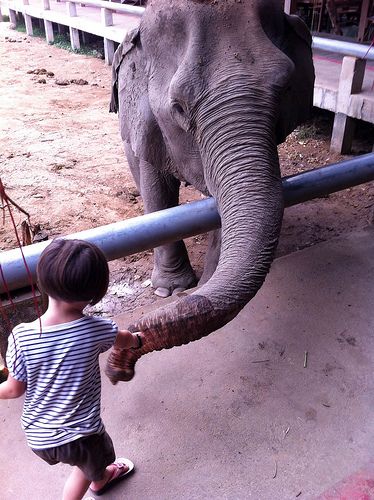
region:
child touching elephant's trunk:
[15, 229, 296, 460]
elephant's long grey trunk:
[93, 114, 319, 392]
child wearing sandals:
[87, 450, 144, 497]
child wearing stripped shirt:
[0, 319, 147, 449]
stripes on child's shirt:
[31, 345, 67, 392]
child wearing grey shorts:
[27, 433, 122, 476]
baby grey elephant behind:
[89, 2, 330, 300]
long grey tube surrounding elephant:
[0, 107, 369, 298]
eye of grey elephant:
[170, 94, 188, 122]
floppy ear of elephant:
[272, 10, 334, 146]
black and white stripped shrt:
[6, 316, 119, 438]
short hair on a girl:
[31, 239, 110, 309]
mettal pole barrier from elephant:
[6, 140, 372, 267]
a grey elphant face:
[131, 0, 320, 191]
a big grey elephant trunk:
[104, 134, 304, 377]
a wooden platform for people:
[2, 1, 372, 126]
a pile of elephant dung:
[22, 59, 55, 78]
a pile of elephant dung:
[55, 78, 69, 86]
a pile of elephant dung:
[5, 36, 28, 45]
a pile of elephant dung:
[38, 78, 47, 84]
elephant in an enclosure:
[101, 2, 335, 482]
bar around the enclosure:
[3, 153, 365, 276]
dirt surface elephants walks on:
[1, 42, 324, 239]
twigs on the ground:
[262, 426, 297, 492]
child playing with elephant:
[5, 237, 151, 480]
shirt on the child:
[9, 307, 106, 436]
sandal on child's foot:
[96, 454, 136, 488]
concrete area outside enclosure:
[6, 1, 366, 98]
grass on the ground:
[296, 125, 322, 142]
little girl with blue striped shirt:
[2, 242, 144, 497]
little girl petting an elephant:
[0, 240, 144, 498]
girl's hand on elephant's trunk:
[129, 329, 147, 349]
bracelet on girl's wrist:
[132, 332, 141, 350]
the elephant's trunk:
[103, 115, 280, 384]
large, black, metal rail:
[2, 151, 372, 297]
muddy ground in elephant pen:
[0, 23, 372, 315]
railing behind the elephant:
[67, 0, 371, 89]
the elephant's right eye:
[172, 100, 185, 117]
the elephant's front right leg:
[142, 165, 196, 295]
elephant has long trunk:
[139, 66, 288, 332]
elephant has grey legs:
[128, 147, 218, 295]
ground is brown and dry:
[29, 27, 105, 229]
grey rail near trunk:
[40, 180, 373, 272]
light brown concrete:
[197, 278, 366, 493]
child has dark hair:
[46, 250, 102, 300]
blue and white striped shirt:
[4, 323, 147, 436]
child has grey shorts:
[43, 422, 121, 477]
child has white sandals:
[86, 454, 129, 497]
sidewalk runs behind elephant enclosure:
[15, 8, 371, 165]